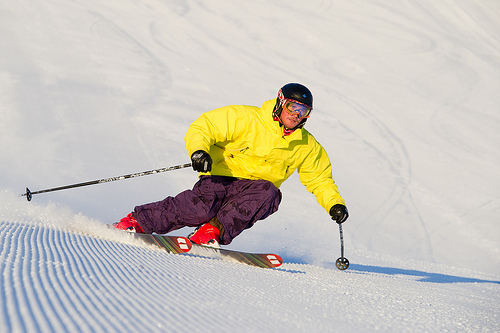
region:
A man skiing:
[21, 74, 388, 267]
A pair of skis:
[95, 229, 291, 276]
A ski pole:
[7, 95, 204, 206]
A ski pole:
[327, 206, 367, 274]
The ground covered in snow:
[1, 5, 498, 322]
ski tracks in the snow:
[143, 5, 446, 263]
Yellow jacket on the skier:
[183, 90, 347, 210]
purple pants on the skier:
[130, 174, 285, 249]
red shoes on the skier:
[118, 205, 225, 249]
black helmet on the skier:
[268, 78, 327, 113]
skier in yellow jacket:
[182, 96, 346, 212]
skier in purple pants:
[131, 174, 281, 244]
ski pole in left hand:
[337, 221, 349, 272]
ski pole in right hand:
[19, 160, 190, 202]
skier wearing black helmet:
[271, 82, 312, 127]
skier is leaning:
[16, 80, 346, 270]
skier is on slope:
[1, 1, 498, 331]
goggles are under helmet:
[280, 98, 310, 115]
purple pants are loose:
[132, 176, 282, 246]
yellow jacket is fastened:
[183, 96, 345, 214]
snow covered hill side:
[7, 3, 494, 328]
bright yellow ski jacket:
[177, 87, 349, 249]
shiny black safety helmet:
[263, 72, 320, 133]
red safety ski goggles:
[272, 91, 323, 121]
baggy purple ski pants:
[119, 166, 284, 241]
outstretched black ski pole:
[15, 151, 207, 216]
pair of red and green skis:
[100, 212, 287, 272]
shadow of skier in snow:
[267, 234, 497, 301]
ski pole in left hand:
[326, 204, 356, 286]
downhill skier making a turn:
[115, 62, 368, 277]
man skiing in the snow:
[19, 74, 349, 271]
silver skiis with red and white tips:
[133, 231, 285, 271]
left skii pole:
[337, 219, 347, 269]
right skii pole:
[21, 163, 190, 198]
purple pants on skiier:
[137, 172, 283, 244]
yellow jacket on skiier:
[185, 101, 349, 226]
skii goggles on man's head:
[278, 87, 311, 116]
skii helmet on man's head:
[274, 82, 311, 112]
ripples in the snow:
[0, 219, 215, 331]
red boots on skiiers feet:
[111, 212, 224, 251]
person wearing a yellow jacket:
[94, 64, 360, 270]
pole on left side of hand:
[325, 197, 357, 277]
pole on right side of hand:
[10, 145, 215, 210]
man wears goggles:
[258, 73, 325, 149]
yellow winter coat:
[175, 98, 350, 208]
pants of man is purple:
[107, 73, 363, 264]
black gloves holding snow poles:
[180, 140, 355, 226]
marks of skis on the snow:
[336, 95, 482, 261]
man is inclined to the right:
[110, 55, 366, 278]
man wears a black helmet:
[246, 59, 333, 153]